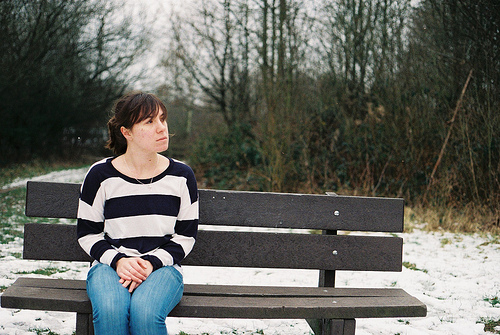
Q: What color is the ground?
A: White.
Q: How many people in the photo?
A: One woman.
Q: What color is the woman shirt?
A: Black and white.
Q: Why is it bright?
A: Sunny.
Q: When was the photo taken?
A: Daytime.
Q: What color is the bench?
A: Brown.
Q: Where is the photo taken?
A: On a bench.